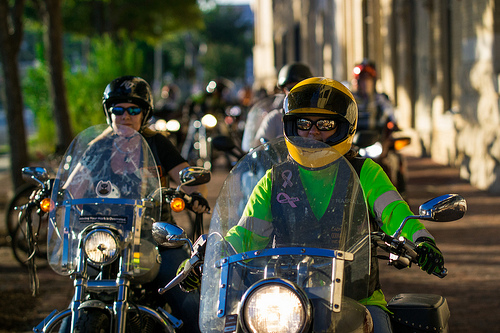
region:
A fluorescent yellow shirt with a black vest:
[261, 159, 426, 232]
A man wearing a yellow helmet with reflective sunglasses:
[275, 106, 357, 168]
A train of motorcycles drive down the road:
[95, 70, 395, 185]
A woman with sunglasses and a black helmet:
[90, 70, 185, 171]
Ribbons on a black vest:
[255, 156, 301, 211]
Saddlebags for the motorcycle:
[365, 285, 440, 330]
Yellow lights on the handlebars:
[146, 180, 207, 215]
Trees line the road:
[10, 0, 210, 155]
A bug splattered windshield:
[225, 146, 375, 256]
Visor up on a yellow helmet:
[273, 78, 358, 138]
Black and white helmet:
[260, 64, 390, 196]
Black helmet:
[84, 80, 165, 155]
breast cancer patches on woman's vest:
[255, 144, 307, 229]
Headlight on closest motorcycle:
[206, 240, 365, 332]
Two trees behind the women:
[4, 5, 187, 150]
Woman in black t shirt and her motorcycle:
[20, 53, 207, 324]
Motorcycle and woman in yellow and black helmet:
[177, 47, 454, 332]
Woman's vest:
[259, 145, 384, 306]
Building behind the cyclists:
[248, 0, 495, 180]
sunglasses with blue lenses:
[107, 99, 142, 119]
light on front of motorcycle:
[238, 251, 331, 332]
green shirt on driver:
[226, 141, 405, 275]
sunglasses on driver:
[291, 116, 337, 138]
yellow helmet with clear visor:
[281, 64, 394, 156]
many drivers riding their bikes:
[63, 53, 413, 243]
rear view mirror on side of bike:
[171, 160, 212, 204]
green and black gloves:
[406, 228, 453, 287]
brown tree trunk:
[38, 53, 100, 130]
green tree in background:
[70, 51, 108, 114]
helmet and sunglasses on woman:
[96, 73, 158, 142]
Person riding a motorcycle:
[191, 70, 482, 330]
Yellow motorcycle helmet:
[266, 62, 369, 169]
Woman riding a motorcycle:
[13, 52, 210, 215]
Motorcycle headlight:
[78, 226, 124, 270]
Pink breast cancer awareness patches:
[267, 163, 298, 215]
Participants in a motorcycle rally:
[28, 50, 471, 330]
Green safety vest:
[196, 149, 445, 251]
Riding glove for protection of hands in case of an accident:
[407, 233, 458, 289]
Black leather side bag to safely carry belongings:
[380, 275, 470, 330]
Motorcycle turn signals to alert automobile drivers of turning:
[33, 190, 189, 211]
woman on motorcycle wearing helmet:
[33, 77, 211, 328]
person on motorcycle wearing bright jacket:
[230, 84, 438, 330]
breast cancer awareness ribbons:
[273, 163, 304, 215]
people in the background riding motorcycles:
[148, 66, 404, 184]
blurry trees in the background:
[6, 6, 237, 159]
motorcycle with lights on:
[51, 128, 216, 327]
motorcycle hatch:
[391, 288, 448, 331]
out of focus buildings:
[351, 1, 496, 187]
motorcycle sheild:
[220, 147, 370, 331]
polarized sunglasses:
[106, 99, 154, 119]